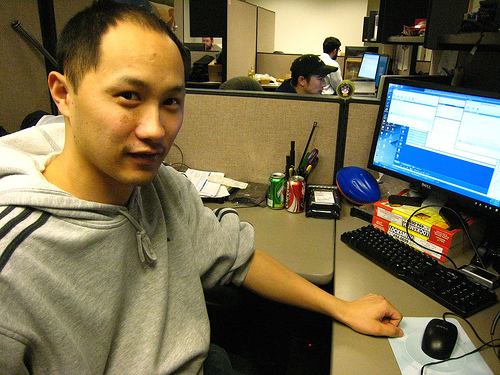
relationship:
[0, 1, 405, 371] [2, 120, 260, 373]
man wearing hoodie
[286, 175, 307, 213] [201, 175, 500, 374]
cup on table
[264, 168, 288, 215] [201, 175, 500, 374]
soda can on table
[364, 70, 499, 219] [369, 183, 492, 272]
computer monitor standing on books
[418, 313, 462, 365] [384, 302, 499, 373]
mouse on mouse pad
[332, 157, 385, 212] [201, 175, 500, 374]
football on table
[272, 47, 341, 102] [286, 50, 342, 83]
man wearing hat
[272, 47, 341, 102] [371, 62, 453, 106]
man working on computer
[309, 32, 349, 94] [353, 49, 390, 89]
man working on computer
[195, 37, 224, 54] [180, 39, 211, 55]
man working on computer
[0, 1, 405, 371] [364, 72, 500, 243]
man working on computer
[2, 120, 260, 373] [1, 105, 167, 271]
hoodie has hood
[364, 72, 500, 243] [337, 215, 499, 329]
computer has keyboard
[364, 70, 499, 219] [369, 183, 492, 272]
computer monitor on books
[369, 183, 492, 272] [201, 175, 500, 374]
books are on table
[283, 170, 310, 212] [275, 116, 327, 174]
cup has pencils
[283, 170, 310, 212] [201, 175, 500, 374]
cup on table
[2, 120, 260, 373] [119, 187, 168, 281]
hoodie has drawstring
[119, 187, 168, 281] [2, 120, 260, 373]
drawstring on front of hoodie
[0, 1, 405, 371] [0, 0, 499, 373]
man in office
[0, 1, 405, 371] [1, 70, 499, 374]
man in cubicle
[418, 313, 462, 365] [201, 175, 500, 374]
mouse on table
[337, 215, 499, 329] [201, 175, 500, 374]
keyboard on table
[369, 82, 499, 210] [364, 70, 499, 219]
computer monitor on computer monitor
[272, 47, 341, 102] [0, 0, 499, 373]
man in office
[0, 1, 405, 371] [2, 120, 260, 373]
man has hoodie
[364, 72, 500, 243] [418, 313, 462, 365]
computer has mouse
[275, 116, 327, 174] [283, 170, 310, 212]
pencils in cup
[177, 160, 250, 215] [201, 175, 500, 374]
papers on table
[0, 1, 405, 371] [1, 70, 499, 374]
man sitting in cubicle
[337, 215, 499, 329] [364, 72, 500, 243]
keyboard connected to computer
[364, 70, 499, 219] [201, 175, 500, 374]
computer monitor on table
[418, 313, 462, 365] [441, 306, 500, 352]
mouse has wire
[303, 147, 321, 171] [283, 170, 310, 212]
scissor in cup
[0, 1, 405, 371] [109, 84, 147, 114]
man has eye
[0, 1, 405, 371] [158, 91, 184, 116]
man has eye